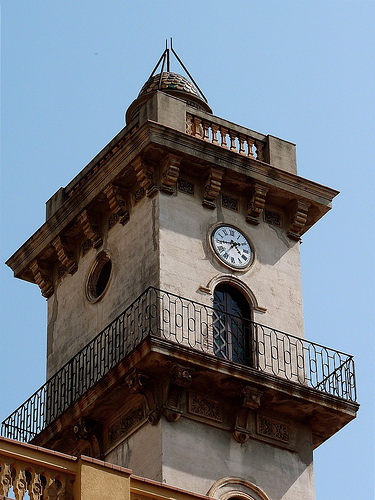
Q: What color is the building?
A: Tan.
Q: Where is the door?
A: On the building.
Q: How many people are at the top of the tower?
A: 0.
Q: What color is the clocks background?
A: White.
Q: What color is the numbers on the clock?
A: Black.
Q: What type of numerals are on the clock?
A: Roman.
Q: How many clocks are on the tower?
A: 1.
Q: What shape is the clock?
A: Circle.